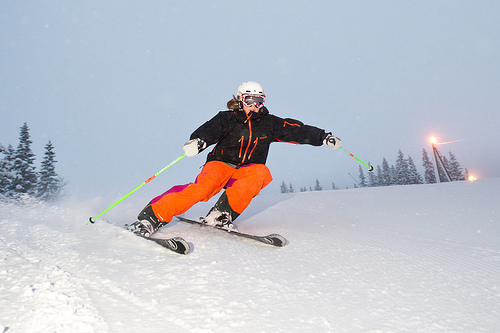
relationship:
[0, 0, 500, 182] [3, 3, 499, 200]
clouds in blue sky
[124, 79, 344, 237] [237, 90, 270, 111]
person wearing snow goggles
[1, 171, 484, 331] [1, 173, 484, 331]
snow covering ground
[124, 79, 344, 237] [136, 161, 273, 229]
person wearing pant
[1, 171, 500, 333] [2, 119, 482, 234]
snow splashing in background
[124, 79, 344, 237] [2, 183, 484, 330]
person skiing down hill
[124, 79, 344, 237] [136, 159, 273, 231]
person wearing pants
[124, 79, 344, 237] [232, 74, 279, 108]
person wearing a helmet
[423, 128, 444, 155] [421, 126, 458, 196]
light on top of a tree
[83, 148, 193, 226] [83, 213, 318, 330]
pole in snow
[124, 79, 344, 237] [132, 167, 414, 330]
person on hill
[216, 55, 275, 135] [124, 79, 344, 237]
pant worn by person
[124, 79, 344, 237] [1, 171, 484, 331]
person skiing on snow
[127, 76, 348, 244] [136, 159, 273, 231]
person wearing pants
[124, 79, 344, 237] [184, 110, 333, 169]
person wearing jacket